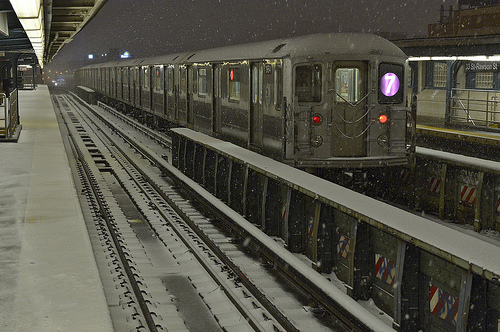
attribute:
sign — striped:
[335, 232, 356, 262]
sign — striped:
[456, 182, 478, 205]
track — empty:
[51, 85, 293, 331]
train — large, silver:
[74, 30, 418, 169]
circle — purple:
[379, 73, 401, 97]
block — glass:
[434, 71, 440, 77]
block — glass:
[477, 74, 480, 80]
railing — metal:
[446, 87, 499, 129]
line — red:
[431, 292, 452, 315]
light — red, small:
[310, 114, 324, 127]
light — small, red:
[378, 115, 390, 127]